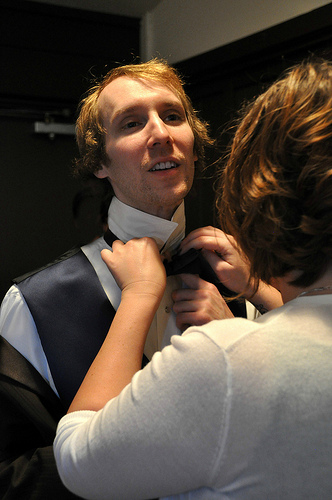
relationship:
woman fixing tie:
[54, 62, 331, 499] [104, 228, 202, 276]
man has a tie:
[1, 55, 264, 499] [104, 228, 202, 276]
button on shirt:
[163, 304, 175, 314] [1, 195, 262, 398]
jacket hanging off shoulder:
[0, 335, 85, 498] [1, 240, 109, 338]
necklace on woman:
[297, 285, 332, 299] [54, 62, 331, 499]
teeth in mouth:
[151, 159, 179, 170] [146, 155, 184, 178]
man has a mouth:
[1, 55, 264, 499] [146, 155, 184, 178]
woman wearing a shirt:
[54, 62, 331, 499] [53, 293, 331, 499]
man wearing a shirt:
[1, 55, 264, 499] [1, 195, 262, 398]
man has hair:
[1, 55, 264, 499] [75, 55, 215, 182]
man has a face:
[1, 55, 264, 499] [98, 75, 196, 209]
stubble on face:
[109, 148, 196, 208] [98, 75, 196, 209]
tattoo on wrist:
[254, 302, 268, 314] [245, 280, 284, 314]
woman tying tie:
[54, 62, 331, 499] [104, 228, 202, 276]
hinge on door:
[3, 105, 79, 140] [1, 106, 114, 303]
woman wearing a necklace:
[54, 62, 331, 499] [297, 285, 332, 299]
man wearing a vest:
[1, 55, 264, 499] [13, 244, 249, 408]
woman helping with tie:
[54, 62, 331, 499] [104, 228, 202, 276]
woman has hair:
[54, 62, 331, 499] [200, 47, 330, 305]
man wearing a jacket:
[1, 55, 264, 499] [0, 335, 85, 498]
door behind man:
[1, 106, 114, 303] [1, 55, 264, 499]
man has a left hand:
[1, 55, 264, 499] [172, 272, 236, 328]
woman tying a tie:
[54, 62, 331, 499] [104, 228, 202, 276]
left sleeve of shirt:
[53, 331, 227, 498] [53, 293, 331, 499]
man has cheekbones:
[1, 55, 264, 499] [109, 120, 196, 162]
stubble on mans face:
[109, 148, 196, 208] [98, 75, 196, 209]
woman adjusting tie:
[54, 62, 331, 499] [104, 228, 202, 276]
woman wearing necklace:
[54, 62, 331, 499] [297, 285, 332, 299]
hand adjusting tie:
[99, 237, 169, 294] [104, 228, 202, 276]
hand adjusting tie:
[178, 225, 253, 293] [104, 228, 202, 276]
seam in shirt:
[178, 326, 232, 487] [53, 293, 331, 499]